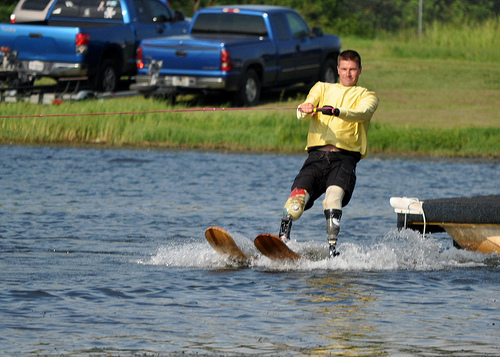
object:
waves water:
[123, 224, 499, 274]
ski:
[253, 231, 300, 263]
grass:
[1, 94, 498, 153]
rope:
[0, 107, 340, 119]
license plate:
[26, 59, 44, 72]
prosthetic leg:
[277, 158, 322, 235]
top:
[296, 80, 379, 157]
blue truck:
[0, 0, 193, 93]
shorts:
[290, 143, 361, 210]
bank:
[0, 115, 499, 164]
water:
[6, 276, 202, 342]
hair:
[335, 49, 361, 67]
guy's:
[278, 49, 379, 258]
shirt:
[295, 81, 380, 159]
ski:
[203, 225, 248, 262]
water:
[99, 175, 184, 213]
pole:
[417, 0, 422, 44]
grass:
[376, 39, 488, 127]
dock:
[388, 195, 500, 254]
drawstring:
[317, 145, 339, 165]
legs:
[320, 164, 353, 241]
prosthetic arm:
[334, 91, 380, 125]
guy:
[277, 49, 381, 259]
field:
[0, 0, 499, 157]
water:
[244, 293, 497, 355]